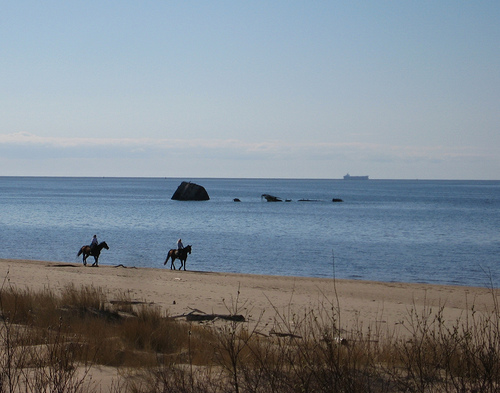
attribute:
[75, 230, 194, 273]
two people — horseback riding, on the beach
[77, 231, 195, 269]
two people — on the beach, horseback riding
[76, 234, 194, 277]
two people — on the beach, horseback riding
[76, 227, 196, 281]
two people — horseback riding, on the beach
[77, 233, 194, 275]
two horses — on the beach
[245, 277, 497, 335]
sand — of beach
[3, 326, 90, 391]
weeds —  Tall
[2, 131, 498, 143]
line —  of clouds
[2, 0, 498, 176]
sky —  Hazy,  mostly clear,  blue, blue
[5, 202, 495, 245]
shallow — of water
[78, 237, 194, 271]
horsemen —  two 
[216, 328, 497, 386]
plants —  dry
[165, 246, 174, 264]
tail —  long,  horse's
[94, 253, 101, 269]
legs —  horse's, the front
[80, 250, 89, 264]
legs — the  back ,  horse's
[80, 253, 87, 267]
legs —  horse's, the back 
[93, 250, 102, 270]
legs — the  front,  horse's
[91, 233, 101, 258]
people —  two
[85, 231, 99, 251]
people —  two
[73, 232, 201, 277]
horses — dark 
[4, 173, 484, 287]
water —  blue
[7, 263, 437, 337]
sand — brown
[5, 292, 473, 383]
grass — brown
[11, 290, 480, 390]
grass — dead